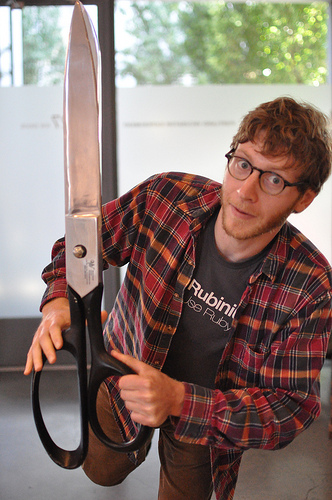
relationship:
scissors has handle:
[23, 0, 157, 478] [24, 284, 147, 480]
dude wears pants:
[18, 91, 331, 499] [71, 354, 222, 500]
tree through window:
[180, 0, 331, 83] [1, 1, 331, 87]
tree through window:
[112, 1, 213, 87] [1, 1, 331, 87]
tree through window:
[21, 6, 66, 83] [1, 1, 331, 87]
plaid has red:
[34, 172, 331, 499] [219, 331, 329, 360]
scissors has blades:
[23, 0, 157, 478] [58, 0, 111, 303]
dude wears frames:
[18, 91, 331, 499] [222, 145, 310, 203]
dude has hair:
[18, 91, 331, 499] [224, 91, 330, 200]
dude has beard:
[18, 91, 331, 499] [212, 184, 302, 248]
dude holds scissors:
[18, 91, 331, 499] [23, 0, 157, 478]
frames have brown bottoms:
[222, 145, 310, 203] [226, 166, 284, 198]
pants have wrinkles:
[71, 354, 222, 500] [158, 423, 213, 500]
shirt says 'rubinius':
[40, 167, 331, 499] [186, 278, 239, 318]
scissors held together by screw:
[23, 0, 157, 478] [70, 243, 91, 263]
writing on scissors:
[82, 254, 96, 291] [23, 0, 157, 478]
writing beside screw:
[82, 254, 96, 291] [70, 243, 91, 263]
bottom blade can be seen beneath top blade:
[82, 1, 111, 206] [61, 1, 105, 212]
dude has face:
[18, 91, 331, 499] [219, 139, 312, 241]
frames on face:
[222, 145, 310, 203] [219, 139, 312, 241]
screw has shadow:
[70, 243, 91, 263] [75, 243, 86, 259]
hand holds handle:
[15, 296, 113, 378] [24, 284, 147, 480]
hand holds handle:
[104, 343, 183, 432] [24, 284, 147, 480]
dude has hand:
[18, 91, 331, 499] [15, 296, 113, 378]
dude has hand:
[18, 91, 331, 499] [104, 343, 183, 432]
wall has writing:
[4, 84, 331, 319] [14, 107, 254, 135]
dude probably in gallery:
[18, 91, 331, 499] [1, 0, 331, 499]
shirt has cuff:
[34, 167, 331, 499] [169, 374, 215, 453]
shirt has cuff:
[34, 167, 331, 499] [37, 277, 71, 313]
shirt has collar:
[34, 167, 331, 499] [172, 182, 292, 289]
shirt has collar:
[40, 167, 331, 499] [207, 210, 278, 268]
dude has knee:
[18, 91, 331, 499] [80, 400, 152, 491]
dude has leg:
[18, 91, 331, 499] [151, 421, 222, 499]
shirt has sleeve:
[34, 167, 331, 499] [173, 219, 330, 456]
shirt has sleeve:
[34, 167, 331, 499] [32, 167, 221, 309]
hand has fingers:
[15, 296, 113, 378] [18, 320, 66, 378]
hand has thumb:
[15, 296, 113, 378] [64, 308, 113, 329]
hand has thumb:
[104, 343, 183, 432] [107, 345, 141, 373]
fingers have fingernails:
[18, 320, 66, 378] [18, 338, 65, 377]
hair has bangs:
[224, 91, 330, 200] [233, 118, 312, 175]